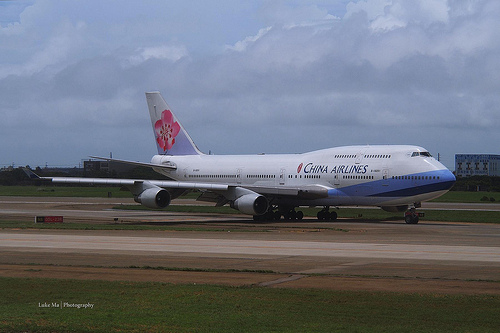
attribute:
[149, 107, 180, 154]
flower — pink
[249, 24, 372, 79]
sky — blue, white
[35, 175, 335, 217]
wing — white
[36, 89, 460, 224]
plane — blue, white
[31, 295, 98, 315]
watermark — photographer's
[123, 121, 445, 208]
windows — long row, small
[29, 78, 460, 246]
china plane — China Airlines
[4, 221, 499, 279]
runway — light brown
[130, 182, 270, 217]
engines — white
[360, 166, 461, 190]
stripe — blue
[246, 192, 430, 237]
wheels — black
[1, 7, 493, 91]
cloud — layered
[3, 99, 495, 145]
cloud — white